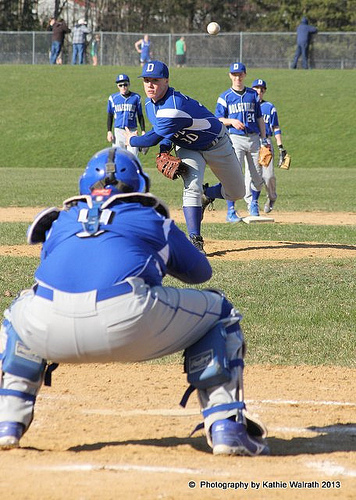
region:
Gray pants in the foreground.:
[1, 294, 247, 420]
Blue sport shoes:
[210, 414, 268, 453]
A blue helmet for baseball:
[76, 144, 144, 189]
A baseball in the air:
[202, 16, 226, 41]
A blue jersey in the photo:
[39, 203, 155, 280]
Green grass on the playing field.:
[241, 273, 346, 342]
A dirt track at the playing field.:
[36, 398, 188, 492]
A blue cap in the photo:
[135, 60, 172, 77]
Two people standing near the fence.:
[44, 11, 90, 62]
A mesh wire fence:
[200, 31, 271, 65]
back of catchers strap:
[64, 203, 112, 246]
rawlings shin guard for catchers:
[176, 343, 230, 382]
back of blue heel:
[200, 416, 248, 469]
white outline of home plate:
[83, 390, 178, 438]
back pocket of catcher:
[97, 317, 151, 363]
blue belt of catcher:
[29, 286, 63, 300]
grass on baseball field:
[237, 284, 309, 365]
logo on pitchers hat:
[134, 59, 158, 73]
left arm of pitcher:
[121, 106, 177, 149]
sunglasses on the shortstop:
[110, 80, 130, 89]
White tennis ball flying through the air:
[202, 20, 220, 37]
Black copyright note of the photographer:
[181, 471, 340, 490]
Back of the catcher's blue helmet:
[68, 142, 151, 199]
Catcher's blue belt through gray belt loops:
[26, 276, 147, 300]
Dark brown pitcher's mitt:
[151, 147, 179, 180]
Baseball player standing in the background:
[214, 57, 260, 222]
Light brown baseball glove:
[254, 142, 269, 166]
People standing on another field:
[33, 5, 189, 64]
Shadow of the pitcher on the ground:
[208, 235, 355, 259]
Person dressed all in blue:
[285, 13, 318, 69]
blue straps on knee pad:
[174, 390, 274, 422]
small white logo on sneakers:
[209, 420, 230, 430]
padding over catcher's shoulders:
[19, 187, 182, 233]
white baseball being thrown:
[195, 18, 239, 42]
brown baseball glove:
[153, 147, 197, 175]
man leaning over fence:
[286, 13, 331, 76]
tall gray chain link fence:
[14, 21, 244, 56]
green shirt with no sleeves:
[166, 38, 200, 60]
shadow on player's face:
[132, 65, 185, 95]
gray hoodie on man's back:
[60, 16, 94, 36]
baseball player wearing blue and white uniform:
[23, 149, 266, 472]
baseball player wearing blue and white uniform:
[138, 65, 204, 155]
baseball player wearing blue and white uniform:
[101, 61, 134, 133]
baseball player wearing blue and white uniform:
[213, 53, 265, 146]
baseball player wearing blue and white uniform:
[256, 71, 282, 135]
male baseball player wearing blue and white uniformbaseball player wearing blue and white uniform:
[37, 143, 162, 420]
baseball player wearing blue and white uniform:
[85, 74, 140, 127]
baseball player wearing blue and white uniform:
[214, 55, 251, 117]